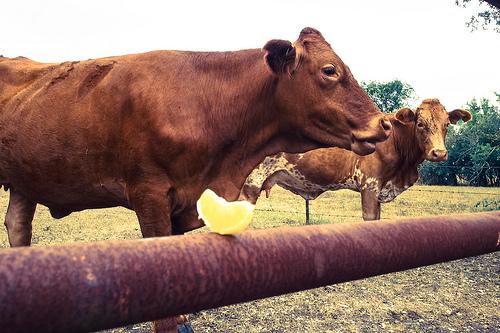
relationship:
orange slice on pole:
[196, 189, 255, 235] [1, 209, 500, 332]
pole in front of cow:
[1, 209, 500, 332] [1, 28, 394, 249]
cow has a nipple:
[237, 98, 472, 229] [265, 186, 272, 198]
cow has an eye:
[1, 28, 394, 249] [321, 65, 338, 77]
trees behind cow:
[354, 1, 500, 187] [237, 98, 472, 229]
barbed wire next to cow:
[256, 165, 500, 220] [237, 98, 472, 229]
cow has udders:
[237, 98, 472, 229] [261, 175, 279, 197]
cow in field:
[1, 28, 394, 249] [1, 0, 500, 333]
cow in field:
[237, 98, 472, 229] [1, 0, 500, 333]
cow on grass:
[1, 28, 394, 249] [1, 184, 500, 331]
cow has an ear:
[1, 28, 394, 249] [263, 37, 302, 76]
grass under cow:
[1, 184, 500, 331] [1, 28, 394, 249]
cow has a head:
[1, 28, 394, 249] [263, 26, 393, 156]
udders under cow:
[261, 175, 279, 197] [237, 98, 472, 229]